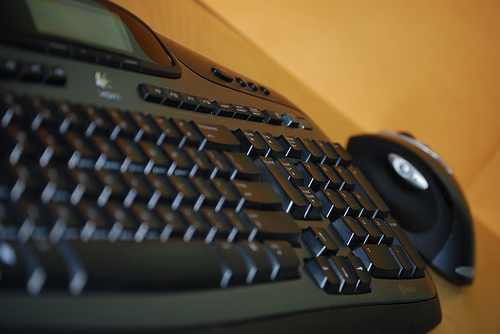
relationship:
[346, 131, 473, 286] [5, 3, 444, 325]
mouse next keyboard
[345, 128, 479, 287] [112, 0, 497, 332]
mouse on desk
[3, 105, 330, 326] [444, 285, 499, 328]
keyboard on desk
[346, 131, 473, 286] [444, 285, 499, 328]
mouse on desk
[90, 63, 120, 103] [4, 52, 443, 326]
logo on keyboard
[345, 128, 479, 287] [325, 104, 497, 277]
mouse to right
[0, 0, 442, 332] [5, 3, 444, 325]
keyboard a keyboard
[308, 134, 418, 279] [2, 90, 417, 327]
numeric keypad part of keyboard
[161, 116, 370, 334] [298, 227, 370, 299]
right left up down aarow keys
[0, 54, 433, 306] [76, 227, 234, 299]
out of focus black space bar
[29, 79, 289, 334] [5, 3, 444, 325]
alphanumeric portion of keyboard